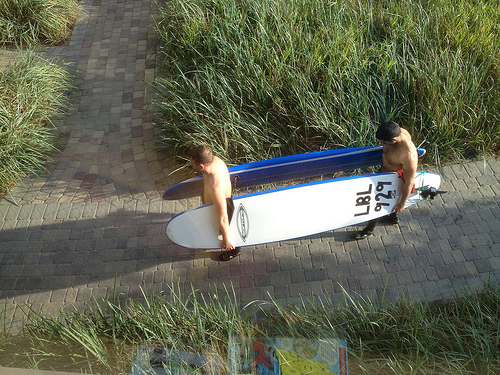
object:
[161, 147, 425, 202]
surfboards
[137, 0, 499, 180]
grass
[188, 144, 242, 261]
dudes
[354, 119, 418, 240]
fellas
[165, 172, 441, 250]
surfboards